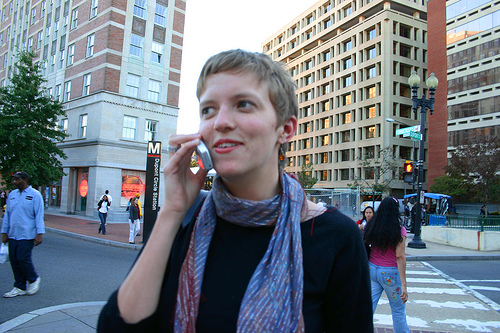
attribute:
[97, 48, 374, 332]
girl — light skinned, talking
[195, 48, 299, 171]
hair — short, blonde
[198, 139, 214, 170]
phone — gray, silver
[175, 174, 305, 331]
scarf — blue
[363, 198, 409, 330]
woman — walking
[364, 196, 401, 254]
hair — long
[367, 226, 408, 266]
shirt — pink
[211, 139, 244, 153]
mouth — red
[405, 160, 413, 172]
traffic light — amber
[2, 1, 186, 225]
building — tall, large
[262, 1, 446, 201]
building — tall, large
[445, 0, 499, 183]
building — tall, large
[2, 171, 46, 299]
man — walking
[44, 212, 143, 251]
corner — brick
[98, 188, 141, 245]
people — walking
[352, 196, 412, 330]
people — walking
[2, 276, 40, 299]
tennis shoes — white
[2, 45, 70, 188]
tree — tall, green, pine